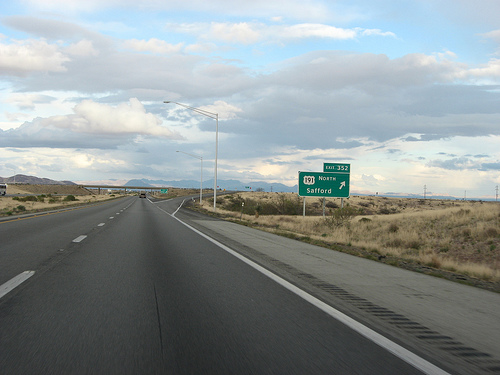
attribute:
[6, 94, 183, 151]
cloud — Part 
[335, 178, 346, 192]
arrow — white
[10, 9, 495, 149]
sky — blue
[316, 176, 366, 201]
lamp — street 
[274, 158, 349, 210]
sign — Safford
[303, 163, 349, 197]
sign — green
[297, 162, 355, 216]
sign — green traffic 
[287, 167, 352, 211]
sign — white traffic, green 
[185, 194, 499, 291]
grass — tall yellow 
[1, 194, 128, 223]
line — yellow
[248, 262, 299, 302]
lines — white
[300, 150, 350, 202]
sign — green 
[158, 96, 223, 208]
lights — street 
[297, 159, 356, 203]
sign — green and white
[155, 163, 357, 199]
signs — green highway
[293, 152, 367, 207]
traffic sign — white , green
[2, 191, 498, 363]
road — long, empty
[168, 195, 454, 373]
line — solid white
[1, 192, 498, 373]
highway — edge 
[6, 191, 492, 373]
paved road — paved , Part 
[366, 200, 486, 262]
grass — green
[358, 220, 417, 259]
grass — green, Part 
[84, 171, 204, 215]
bridge — Part 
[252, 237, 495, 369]
lines — black dash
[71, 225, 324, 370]
highway — side 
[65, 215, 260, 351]
highway — side 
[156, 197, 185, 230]
road — side  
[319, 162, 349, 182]
number — exit 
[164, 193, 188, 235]
road —  side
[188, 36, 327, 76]
sky — blue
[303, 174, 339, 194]
lettering — white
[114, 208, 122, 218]
line — white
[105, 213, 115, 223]
line — white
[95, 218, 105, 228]
line — white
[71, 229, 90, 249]
line — white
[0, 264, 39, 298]
line — white